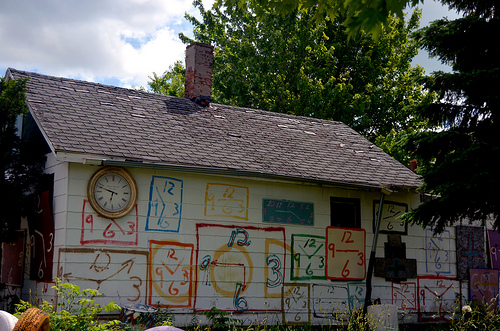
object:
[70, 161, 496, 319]
wall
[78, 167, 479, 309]
art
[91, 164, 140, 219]
clock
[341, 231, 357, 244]
number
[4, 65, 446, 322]
house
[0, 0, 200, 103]
clouds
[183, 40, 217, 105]
chimny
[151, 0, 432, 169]
tree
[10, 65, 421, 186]
roof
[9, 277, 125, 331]
bushes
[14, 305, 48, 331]
wheel